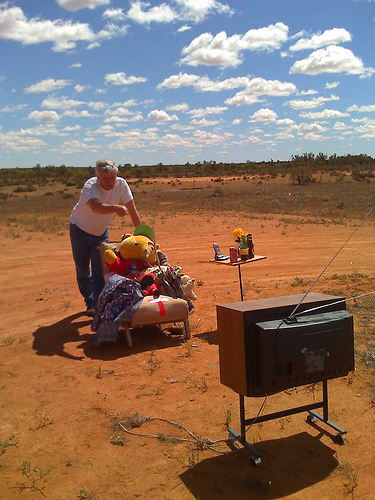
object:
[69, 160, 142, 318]
man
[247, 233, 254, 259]
beer bottle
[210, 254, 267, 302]
table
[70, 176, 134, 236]
shirt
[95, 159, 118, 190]
head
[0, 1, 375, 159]
clouds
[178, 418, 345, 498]
shadow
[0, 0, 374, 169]
sky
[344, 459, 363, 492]
grass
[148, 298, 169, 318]
red tape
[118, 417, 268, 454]
brown rope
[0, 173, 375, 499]
ground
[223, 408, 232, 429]
grass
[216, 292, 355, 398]
television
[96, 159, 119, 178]
hair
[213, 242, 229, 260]
items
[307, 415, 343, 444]
wheels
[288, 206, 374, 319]
antenna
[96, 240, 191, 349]
chair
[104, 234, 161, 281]
bear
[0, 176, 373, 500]
desert